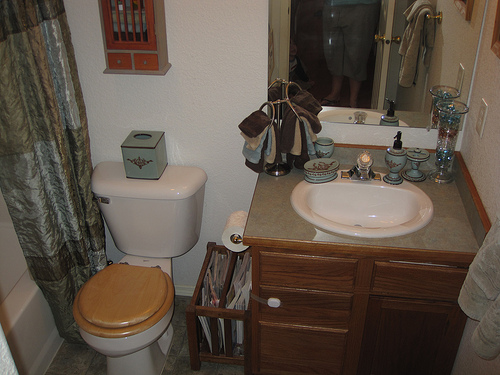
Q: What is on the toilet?
A: A tissue holder.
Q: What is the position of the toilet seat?
A: The seat is down.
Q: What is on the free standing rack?
A: Wash cloths.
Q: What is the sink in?
A: A brown cabinet.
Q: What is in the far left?
A: The bathtub.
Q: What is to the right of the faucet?
A: Hand soap dispenser.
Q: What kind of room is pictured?
A: A bathroom.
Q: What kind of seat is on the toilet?
A: A wooden seat.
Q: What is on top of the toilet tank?
A: A tissue box.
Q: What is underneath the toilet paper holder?
A: A magazine rack.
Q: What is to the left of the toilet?
A: The bathtub.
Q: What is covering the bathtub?
A: A shower curtain.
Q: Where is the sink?
A: On the right side.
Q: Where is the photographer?
A: Reflected on the mirror.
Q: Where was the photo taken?
A: In bathroom.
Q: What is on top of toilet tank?
A: Tissue box.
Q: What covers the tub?
A: Shower curtain.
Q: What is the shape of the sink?
A: Oval.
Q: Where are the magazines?
A: In a rack.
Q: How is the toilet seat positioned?
A: Down.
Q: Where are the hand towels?
A: On counter.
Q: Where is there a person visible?
A: In mirror.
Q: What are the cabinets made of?
A: Wood.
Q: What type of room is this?
A: A bathroom.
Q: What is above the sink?
A: A faucet.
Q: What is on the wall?
A: A mirror.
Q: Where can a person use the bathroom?
A: The toilet.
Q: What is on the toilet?
A: An empty box of tissues.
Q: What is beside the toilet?
A: A roll of toilet paper.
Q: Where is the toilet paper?
A: On the holder.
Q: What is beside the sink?
A: A towel holder.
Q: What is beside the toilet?
A: A magazine rack.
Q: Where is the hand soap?
A: In the soap dispenser.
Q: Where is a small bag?
A: On the sink.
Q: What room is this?
A: Bathroom.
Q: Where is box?
A: On the toilet.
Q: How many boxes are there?
A: One.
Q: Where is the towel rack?
A: Sink.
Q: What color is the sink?
A: White.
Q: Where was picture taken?
A: Bathroom.